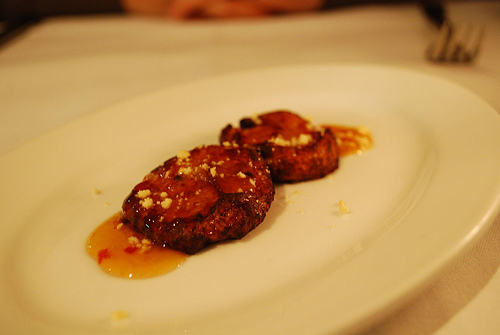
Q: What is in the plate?
A: Sauteed steak.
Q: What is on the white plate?
A: Sauteed meat.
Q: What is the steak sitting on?
A: A plate.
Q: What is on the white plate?
A: Steak.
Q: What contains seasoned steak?
A: Dinner plate.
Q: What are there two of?
A: Pieces of steak.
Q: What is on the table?
A: A meat dish.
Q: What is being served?
A: Steak.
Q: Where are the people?
A: No people.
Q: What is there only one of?
A: A plate.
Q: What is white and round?
A: Plate.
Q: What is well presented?
A: The appetizer.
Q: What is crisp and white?
A: Tablecloth.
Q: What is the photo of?
A: Some food.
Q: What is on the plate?
A: Meat.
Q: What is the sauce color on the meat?
A: Brown.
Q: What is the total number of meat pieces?
A: 2.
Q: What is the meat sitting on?
A: Plate.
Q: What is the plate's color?
A: White.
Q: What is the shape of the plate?
A: Oval.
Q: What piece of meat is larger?
A: The one on the left.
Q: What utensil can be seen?
A: Fork.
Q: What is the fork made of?
A: Metal.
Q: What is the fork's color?
A: Silver.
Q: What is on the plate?
A: Meat.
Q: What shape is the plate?
A: Oval.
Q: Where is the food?
A: On a plate.